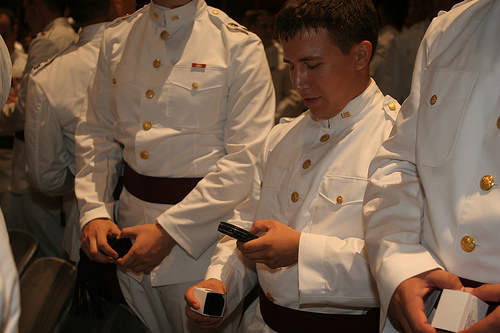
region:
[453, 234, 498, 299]
Gold button on shirt.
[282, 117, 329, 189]
Gold buttons on shirt.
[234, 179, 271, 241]
Man holding cellphone.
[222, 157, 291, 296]
Cellphone in man's left hand.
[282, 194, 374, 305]
Man wearing white shirt.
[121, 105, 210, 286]
Person wearing white shirt.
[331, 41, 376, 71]
Person has dark hair.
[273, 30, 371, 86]
Man has short hair.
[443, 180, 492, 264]
Person wearing white shirt.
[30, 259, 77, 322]
Gray chairs in front of people.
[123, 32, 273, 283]
the hand of a person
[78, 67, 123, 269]
the hand of a person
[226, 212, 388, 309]
the hand of a person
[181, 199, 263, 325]
the hand of a person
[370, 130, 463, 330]
the hand of a person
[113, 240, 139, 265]
the finger of a person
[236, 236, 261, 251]
the finger of a person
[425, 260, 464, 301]
the finger of a person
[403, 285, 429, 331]
the finger of a person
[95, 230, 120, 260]
the finger of a person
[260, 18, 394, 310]
A short man standing between tall men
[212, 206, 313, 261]
A hand operating a smart phone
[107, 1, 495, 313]
Men in white uniforms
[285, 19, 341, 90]
Sweat glistening on a man's face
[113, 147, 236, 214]
A belt around a man's waist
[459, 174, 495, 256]
Shiny brass buttons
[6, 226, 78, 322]
The backs of two chairs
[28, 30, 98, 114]
The back side of a man's shoulder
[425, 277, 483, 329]
A small box held in a man's hands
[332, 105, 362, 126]
A US pin on a man's collar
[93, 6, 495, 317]
men in white uniforms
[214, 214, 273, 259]
cell phone in hand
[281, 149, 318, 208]
gold buttons on uniform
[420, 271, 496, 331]
white box in hands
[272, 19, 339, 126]
man looking down at phone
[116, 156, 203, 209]
wide black uniform belt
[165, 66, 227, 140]
pocket on front of uniform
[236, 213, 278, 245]
thumb pushing phone button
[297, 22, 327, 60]
shine on sweaty face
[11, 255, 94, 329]
back of gray chair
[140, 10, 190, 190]
gold buttons going down a shirt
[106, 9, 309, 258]
white button down shirt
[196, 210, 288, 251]
a black cell phone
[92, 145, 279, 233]
a belt over a white shirt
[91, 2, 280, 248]
a long sleeve shirt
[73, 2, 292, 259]
a white shirt with gold buttons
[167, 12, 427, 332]
a man holding his cell phone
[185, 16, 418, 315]
a man looking at his cell phone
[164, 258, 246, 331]
a hand holding a box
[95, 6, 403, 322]
one short guy next to a tall guy